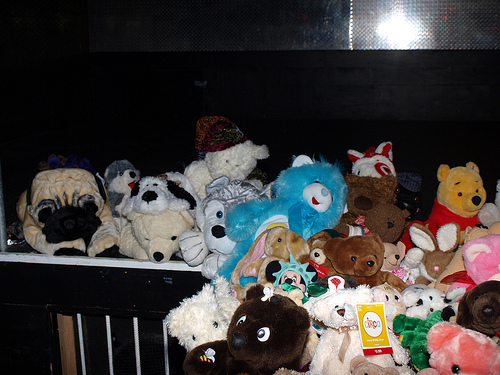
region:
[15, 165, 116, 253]
Stuffed dog with wrinkled face in pile of stuffed animals.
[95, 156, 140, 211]
Stuffed grey husky dog in pile of stuffed animals.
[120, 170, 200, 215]
Stuffed white dog with floppy ears.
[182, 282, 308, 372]
Stuffed brown bear with two bees on it.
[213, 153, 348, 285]
Stuffed blue bear in pile of stuffed animals.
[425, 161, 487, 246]
Stuffed yellow bear in red shirt.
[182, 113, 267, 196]
Stuffed white bear in stocking cap.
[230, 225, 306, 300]
Stuffed brown rabbit with long ears.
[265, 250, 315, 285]
Stuffed mouse with green, spiked crown on head.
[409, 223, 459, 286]
Stuffed brown rabbit with pink nose.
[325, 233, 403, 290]
a brown fluffy stuffed animal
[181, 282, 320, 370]
a brown fluffy stuffed animal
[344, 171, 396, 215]
a brown fluffy stuffed animal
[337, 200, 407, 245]
a brown fluffy stuffed animal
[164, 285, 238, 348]
a white fluffy stuffed animal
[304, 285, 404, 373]
a white fluffy stuffed animal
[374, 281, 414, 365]
a white fluffy stuffed animal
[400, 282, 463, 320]
a white fluffy stuffed animal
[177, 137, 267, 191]
a white fluffy stuffed animal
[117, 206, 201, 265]
a white fluffy stuffed animal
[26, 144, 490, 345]
bunch of stuffed animals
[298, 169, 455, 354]
Stuffed bears of many colors and sizes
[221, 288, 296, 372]
A stuffed brown bear with large eyes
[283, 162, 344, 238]
A stuffed blue bear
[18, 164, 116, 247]
A tan and black stuffed dog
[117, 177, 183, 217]
A small white stuffed dog with black ears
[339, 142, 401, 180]
A red and white dog that is stuffed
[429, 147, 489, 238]
A bear called winnie the pooh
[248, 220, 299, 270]
A tan stuffed bunny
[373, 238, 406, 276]
A stuffed animal that looks like a mouse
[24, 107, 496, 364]
large group of stuffed animals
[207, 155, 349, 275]
blue teddy bear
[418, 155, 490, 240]
winnie the pooh bear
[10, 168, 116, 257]
beige and black pug stuffed animal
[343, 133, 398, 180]
black and white stuffed animal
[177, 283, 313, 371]
dark brown teddy bear in foreground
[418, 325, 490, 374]
pink bear in corner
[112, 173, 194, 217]
black and white dog stuffed animal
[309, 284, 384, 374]
all white teddy bear with neck ribbon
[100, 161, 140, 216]
gray and white wolf stuffed animal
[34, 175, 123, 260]
tan and black bull dog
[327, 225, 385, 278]
small brown teddy bear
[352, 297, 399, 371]
a range and red tag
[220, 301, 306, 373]
dark brown colored bear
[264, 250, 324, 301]
mickey mouse dressed as statue of liberty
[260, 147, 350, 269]
bright blue care bear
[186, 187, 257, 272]
gray and white wolf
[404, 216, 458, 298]
brown and white bunny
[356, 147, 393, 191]
red and white target dog